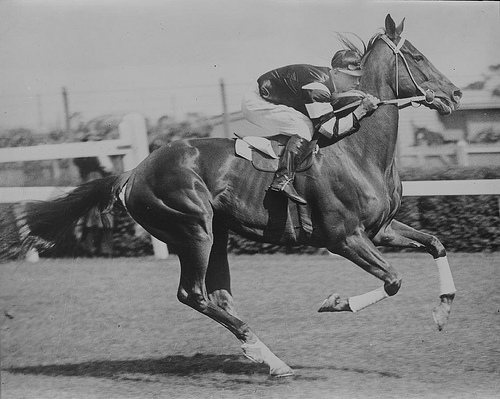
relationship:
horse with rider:
[130, 14, 466, 374] [245, 50, 373, 189]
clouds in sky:
[30, 14, 264, 106] [9, 6, 362, 130]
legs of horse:
[139, 194, 294, 379] [130, 14, 466, 374]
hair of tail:
[8, 200, 91, 259] [15, 161, 119, 263]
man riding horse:
[232, 49, 380, 206] [130, 14, 466, 374]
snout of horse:
[422, 65, 465, 120] [130, 14, 466, 374]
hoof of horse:
[316, 294, 345, 316] [130, 14, 466, 374]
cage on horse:
[221, 163, 288, 236] [130, 14, 466, 374]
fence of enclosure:
[6, 126, 173, 254] [11, 122, 491, 236]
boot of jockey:
[265, 136, 305, 207] [229, 44, 365, 201]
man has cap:
[232, 49, 380, 206] [333, 43, 363, 73]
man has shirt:
[232, 49, 380, 206] [258, 63, 362, 135]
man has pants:
[232, 49, 364, 202] [239, 87, 320, 153]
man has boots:
[232, 49, 380, 206] [269, 140, 315, 205]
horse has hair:
[0, 12, 463, 384] [0, 174, 120, 261]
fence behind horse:
[0, 111, 169, 261] [130, 14, 466, 374]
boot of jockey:
[265, 135, 317, 205] [241, 47, 385, 212]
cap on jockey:
[332, 49, 365, 76] [241, 47, 385, 212]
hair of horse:
[0, 174, 120, 261] [0, 12, 463, 384]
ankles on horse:
[339, 282, 389, 317] [0, 12, 463, 384]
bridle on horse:
[372, 30, 436, 106] [0, 12, 463, 384]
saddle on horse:
[236, 125, 323, 173] [0, 12, 463, 384]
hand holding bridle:
[351, 90, 382, 122] [373, 29, 436, 108]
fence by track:
[0, 111, 169, 261] [3, 255, 483, 396]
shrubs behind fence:
[401, 161, 484, 251] [2, 109, 483, 261]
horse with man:
[0, 12, 463, 384] [232, 49, 380, 206]